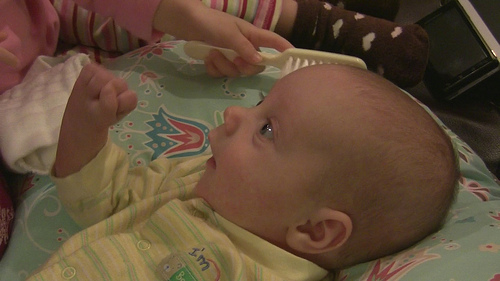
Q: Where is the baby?
A: On a bed.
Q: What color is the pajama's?
A: Yellow.